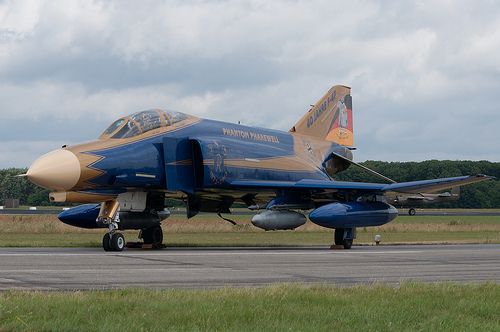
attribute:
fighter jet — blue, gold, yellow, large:
[14, 81, 496, 253]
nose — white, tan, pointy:
[13, 147, 81, 195]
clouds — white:
[1, 0, 497, 162]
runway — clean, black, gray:
[5, 242, 500, 285]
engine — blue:
[311, 198, 403, 231]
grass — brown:
[6, 212, 500, 247]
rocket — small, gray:
[243, 207, 312, 234]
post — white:
[25, 204, 40, 211]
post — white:
[58, 203, 74, 212]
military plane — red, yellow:
[386, 186, 468, 219]